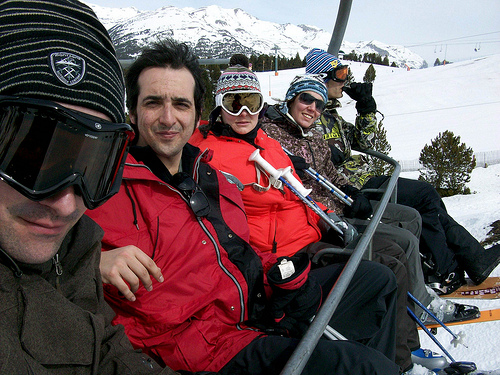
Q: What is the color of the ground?
A: White.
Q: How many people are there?
A: 5.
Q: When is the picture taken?
A: Daytime.